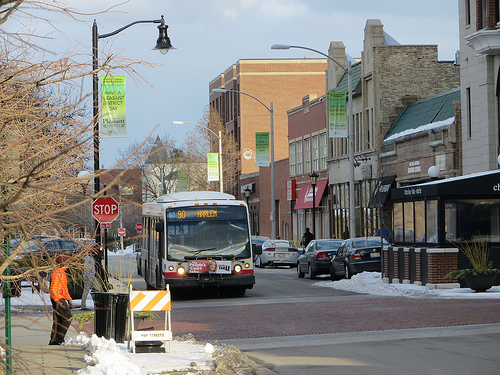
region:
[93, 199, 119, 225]
STOP mentioned on sign board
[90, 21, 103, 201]
street light fixed to black color pole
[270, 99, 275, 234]
street lamp fixed to grey color pole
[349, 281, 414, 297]
snow near corner of road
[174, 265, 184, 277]
head light of the bus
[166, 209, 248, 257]
wind shield of the bus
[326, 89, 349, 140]
advertisement banner hanging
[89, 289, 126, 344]
black color bin kept near road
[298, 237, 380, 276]
car parked at side of road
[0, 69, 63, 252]
branches of trees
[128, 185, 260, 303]
bus on a street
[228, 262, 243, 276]
front headlight on a bus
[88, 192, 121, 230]
red and white sign on a pole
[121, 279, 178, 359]
barricade on a sidewalk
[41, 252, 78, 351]
person with an orange jacket standing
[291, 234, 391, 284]
cars parked on a street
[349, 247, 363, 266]
rear tail light on a vehicle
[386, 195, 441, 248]
windows on a building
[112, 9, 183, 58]
street light on a pole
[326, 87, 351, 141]
banner on a pole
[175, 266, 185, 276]
The front left headlight on the bus.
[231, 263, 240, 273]
The front right headlight of the bus.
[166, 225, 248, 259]
The front window of the bus.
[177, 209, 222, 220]
The marquee display of the bus.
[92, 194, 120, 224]
The stop sign on the pole.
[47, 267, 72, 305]
The orange coat the person is wearing.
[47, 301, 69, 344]
The black pants the person is wearing.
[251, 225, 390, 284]
The cars parked on the right.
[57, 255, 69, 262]
The burgundy hat the person in the orange coat is wearing.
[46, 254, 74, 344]
A person on the sidewalk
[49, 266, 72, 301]
A bright orange jacket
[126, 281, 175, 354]
An orange and white traffic barrier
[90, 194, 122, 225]
A red stop sign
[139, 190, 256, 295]
A bus driving down the street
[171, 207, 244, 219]
A digital sign on the bus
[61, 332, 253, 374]
Snow on the sidewalk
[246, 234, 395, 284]
Cars parked along the road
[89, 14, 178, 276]
A tall black light pole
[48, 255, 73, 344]
man standing on the sidewalk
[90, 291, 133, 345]
trash can next to person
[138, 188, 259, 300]
bus on the street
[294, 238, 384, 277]
two cars parked on the street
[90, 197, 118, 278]
traffic sign on the sidewalk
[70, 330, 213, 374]
snow on the ground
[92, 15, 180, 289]
light hanging from post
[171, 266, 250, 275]
headlights in front of bus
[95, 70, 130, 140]
advertisement hanging from post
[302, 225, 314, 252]
person walking on the sidewalk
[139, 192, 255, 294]
The bus on the road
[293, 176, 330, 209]
The red awning on the building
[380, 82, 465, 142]
The green roof is piled with snow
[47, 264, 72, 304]
orange jacket person is wearing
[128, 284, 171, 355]
yellow and white traffic barrier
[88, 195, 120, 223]
red and white stop sign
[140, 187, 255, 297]
public bus coming down the street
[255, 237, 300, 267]
grey car parked on the side of the street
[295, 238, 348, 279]
black car in back of the grey car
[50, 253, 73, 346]
person waiting for the bus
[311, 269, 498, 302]
snow on the ground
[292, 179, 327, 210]
red and white canopy of the store front